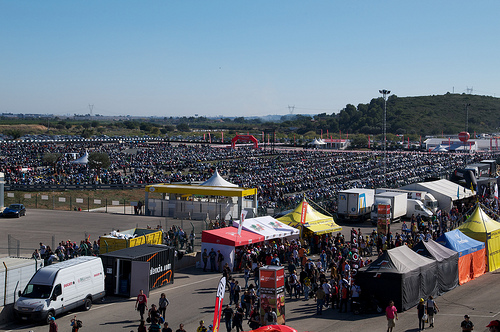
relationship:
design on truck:
[356, 192, 366, 214] [336, 186, 376, 225]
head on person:
[386, 300, 395, 307] [382, 298, 399, 330]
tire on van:
[83, 297, 93, 310] [11, 252, 107, 322]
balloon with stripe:
[456, 127, 471, 144] [454, 130, 471, 138]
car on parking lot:
[0, 204, 30, 224] [1, 203, 209, 281]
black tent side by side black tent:
[419, 235, 461, 292] [367, 245, 436, 307]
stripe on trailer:
[145, 248, 157, 265] [98, 243, 175, 298]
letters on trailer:
[149, 260, 171, 275] [98, 243, 175, 298]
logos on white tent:
[246, 210, 296, 240] [242, 207, 301, 250]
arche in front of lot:
[234, 137, 256, 147] [2, 139, 499, 224]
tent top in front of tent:
[291, 197, 341, 233] [229, 215, 304, 267]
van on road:
[17, 242, 127, 311] [15, 199, 494, 329]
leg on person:
[134, 302, 143, 318] [132, 284, 152, 326]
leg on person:
[381, 314, 400, 329] [380, 301, 404, 330]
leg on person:
[314, 302, 319, 317] [313, 285, 327, 319]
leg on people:
[418, 311, 436, 327] [425, 295, 439, 328]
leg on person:
[386, 320, 398, 330] [368, 294, 408, 329]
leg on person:
[319, 303, 322, 314] [313, 285, 327, 319]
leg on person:
[329, 297, 336, 307] [329, 277, 343, 312]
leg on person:
[297, 290, 308, 302] [285, 267, 306, 295]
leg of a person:
[289, 286, 294, 296] [289, 268, 301, 300]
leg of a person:
[233, 295, 241, 302] [242, 307, 312, 332]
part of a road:
[16, 278, 223, 332] [15, 199, 494, 329]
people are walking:
[418, 316, 453, 332] [352, 293, 462, 332]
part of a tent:
[135, 202, 341, 304] [345, 236, 430, 304]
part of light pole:
[253, 130, 450, 323] [375, 85, 392, 189]